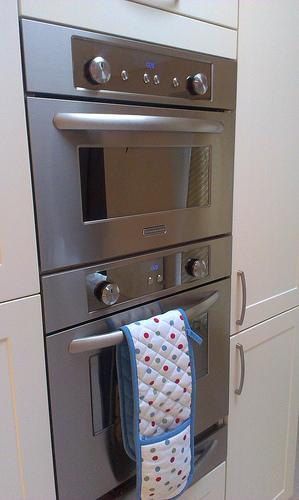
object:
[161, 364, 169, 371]
polka dots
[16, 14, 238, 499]
pair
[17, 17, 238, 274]
oven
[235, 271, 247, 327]
handles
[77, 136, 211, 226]
window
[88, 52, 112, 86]
knobs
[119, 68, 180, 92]
display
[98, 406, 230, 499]
bottom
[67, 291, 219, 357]
hanging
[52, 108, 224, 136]
handles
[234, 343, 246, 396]
handles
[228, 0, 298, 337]
cupboard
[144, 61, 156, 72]
time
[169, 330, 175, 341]
dots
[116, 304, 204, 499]
mit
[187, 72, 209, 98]
dial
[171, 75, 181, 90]
buttons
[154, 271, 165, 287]
buttons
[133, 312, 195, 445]
colorful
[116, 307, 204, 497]
towel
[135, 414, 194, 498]
pocket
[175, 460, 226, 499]
drawer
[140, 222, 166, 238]
branding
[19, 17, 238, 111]
on top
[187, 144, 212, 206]
reflection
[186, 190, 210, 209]
stripes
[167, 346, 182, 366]
quilted squares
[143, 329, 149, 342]
red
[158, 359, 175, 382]
partten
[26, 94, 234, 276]
cooker